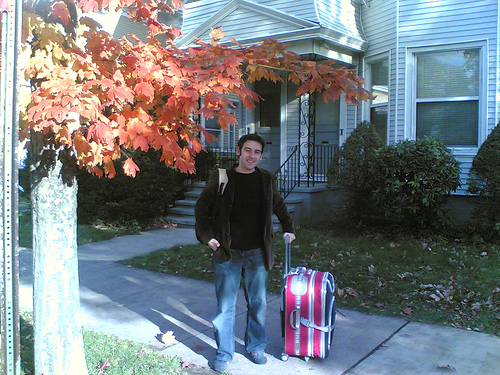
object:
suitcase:
[278, 235, 337, 362]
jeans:
[211, 248, 267, 363]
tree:
[18, 0, 378, 375]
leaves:
[12, 0, 375, 179]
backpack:
[195, 168, 229, 245]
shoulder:
[209, 169, 231, 194]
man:
[194, 134, 296, 372]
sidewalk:
[16, 246, 498, 375]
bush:
[367, 134, 464, 231]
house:
[102, 0, 499, 231]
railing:
[272, 78, 344, 200]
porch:
[202, 54, 339, 185]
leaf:
[155, 328, 177, 347]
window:
[405, 36, 488, 151]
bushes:
[463, 119, 498, 236]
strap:
[218, 167, 229, 195]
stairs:
[161, 181, 312, 232]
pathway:
[76, 226, 200, 261]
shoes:
[208, 352, 237, 370]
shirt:
[229, 167, 265, 251]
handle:
[285, 235, 292, 275]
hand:
[283, 232, 295, 243]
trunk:
[30, 137, 89, 374]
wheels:
[279, 354, 289, 363]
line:
[337, 327, 404, 375]